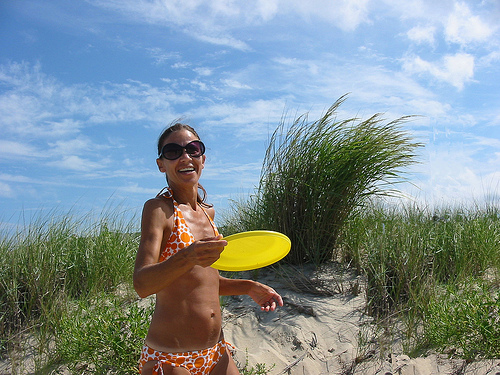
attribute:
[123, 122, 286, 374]
woman — happy, standing, smiling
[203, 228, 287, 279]
frisbee — yellow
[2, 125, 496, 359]
grass — green, tall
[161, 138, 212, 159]
sunglasses — large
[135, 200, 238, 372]
swimsuit — orange, white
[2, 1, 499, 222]
sky — blue, clear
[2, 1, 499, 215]
clouds — white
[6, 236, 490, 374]
dune — sand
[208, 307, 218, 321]
belly button — tiny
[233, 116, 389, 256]
bush — green, tall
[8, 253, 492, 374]
sand — brown